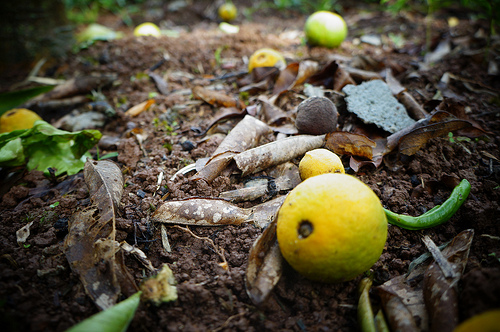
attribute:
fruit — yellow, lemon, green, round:
[275, 172, 388, 279]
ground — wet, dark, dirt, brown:
[0, 1, 499, 329]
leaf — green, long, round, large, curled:
[1, 121, 100, 175]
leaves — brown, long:
[155, 112, 468, 305]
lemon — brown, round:
[294, 97, 338, 134]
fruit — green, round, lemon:
[305, 11, 345, 48]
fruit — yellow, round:
[298, 149, 345, 183]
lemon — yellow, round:
[0, 107, 40, 135]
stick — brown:
[418, 233, 451, 275]